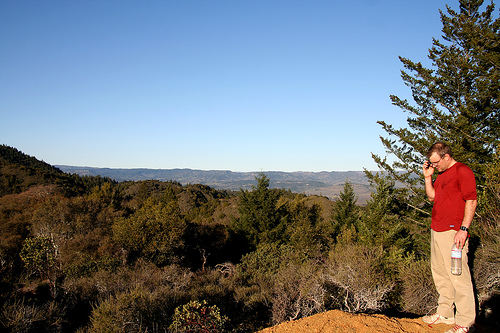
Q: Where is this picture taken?
A: Mountains.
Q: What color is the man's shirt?
A: Red.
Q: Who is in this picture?
A: A man.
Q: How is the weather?
A: Clear.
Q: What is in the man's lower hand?
A: A water bottle.